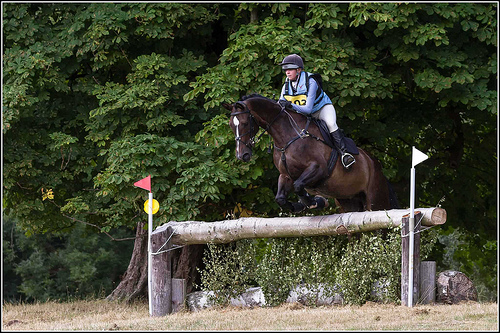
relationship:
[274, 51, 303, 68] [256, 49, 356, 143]
helmet on equestrian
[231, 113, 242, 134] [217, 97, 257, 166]
mark on face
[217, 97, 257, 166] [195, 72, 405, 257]
face of horse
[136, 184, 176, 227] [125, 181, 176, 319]
sign on pole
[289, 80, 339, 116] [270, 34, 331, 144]
jacket on jockey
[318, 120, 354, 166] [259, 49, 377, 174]
boot on jockey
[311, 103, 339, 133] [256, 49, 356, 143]
pants on equestrian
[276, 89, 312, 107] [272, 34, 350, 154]
number on jockey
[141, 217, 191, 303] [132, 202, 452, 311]
stump on horse jump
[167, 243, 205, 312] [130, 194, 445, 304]
stump on horse jump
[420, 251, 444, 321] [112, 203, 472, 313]
stump on horse jump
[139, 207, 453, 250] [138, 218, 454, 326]
stump on horse jump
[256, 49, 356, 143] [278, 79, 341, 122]
equestrian in clothes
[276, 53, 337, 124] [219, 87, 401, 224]
girl riding a horse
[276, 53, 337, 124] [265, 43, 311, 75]
girl in safety helmet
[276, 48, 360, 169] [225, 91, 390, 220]
person on horse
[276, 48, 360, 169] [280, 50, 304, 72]
person wearing helmet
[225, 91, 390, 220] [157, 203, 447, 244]
horse jumping over trunk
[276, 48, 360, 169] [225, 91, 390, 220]
person riding on horse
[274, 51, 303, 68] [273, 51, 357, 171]
helmet on jockey